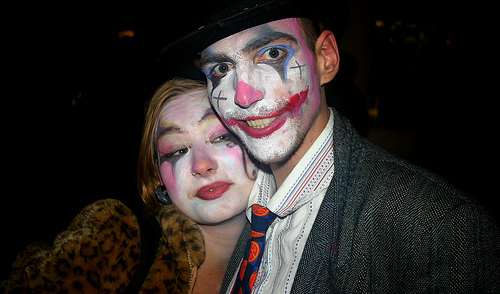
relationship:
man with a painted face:
[196, 17, 499, 289] [195, 19, 322, 164]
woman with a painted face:
[1, 78, 260, 292] [156, 93, 261, 225]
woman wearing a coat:
[1, 78, 260, 292] [2, 199, 206, 294]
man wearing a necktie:
[196, 17, 499, 289] [231, 205, 278, 292]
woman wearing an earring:
[1, 78, 260, 292] [155, 183, 172, 204]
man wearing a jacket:
[196, 17, 499, 289] [290, 107, 500, 292]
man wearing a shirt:
[196, 17, 499, 289] [225, 106, 334, 293]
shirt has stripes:
[225, 106, 334, 293] [276, 131, 338, 216]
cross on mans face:
[292, 61, 306, 78] [195, 19, 322, 164]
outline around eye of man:
[255, 45, 295, 82] [196, 17, 499, 289]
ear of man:
[314, 30, 340, 85] [196, 17, 499, 289]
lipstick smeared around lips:
[221, 89, 310, 138] [236, 112, 289, 136]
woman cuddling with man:
[1, 78, 260, 292] [196, 17, 499, 289]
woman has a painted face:
[1, 78, 260, 292] [156, 93, 261, 225]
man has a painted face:
[196, 17, 499, 289] [195, 19, 322, 164]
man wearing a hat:
[196, 17, 499, 289] [161, 0, 349, 54]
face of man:
[195, 19, 322, 164] [196, 17, 499, 289]